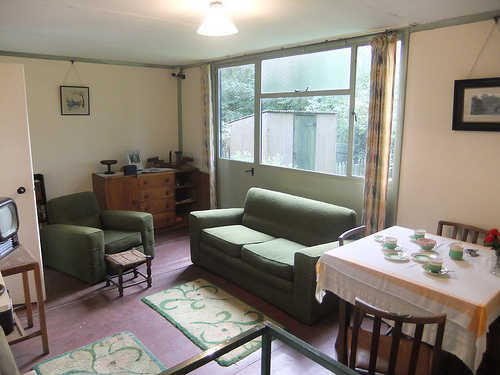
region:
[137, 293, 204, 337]
blue edge of small rug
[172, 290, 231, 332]
blue design on white rug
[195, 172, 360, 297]
large green sofa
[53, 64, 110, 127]
picture hanging on black hook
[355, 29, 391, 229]
tall pink and gray drape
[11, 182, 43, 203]
black door knob on pink door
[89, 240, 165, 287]
small stool with pink cover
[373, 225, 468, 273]
pink and green cups and saucers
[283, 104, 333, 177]
blue door on white shed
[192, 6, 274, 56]
large white light fixture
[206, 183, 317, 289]
green couch by window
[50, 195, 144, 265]
green chair in living room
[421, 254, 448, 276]
tea cup on table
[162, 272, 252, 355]
rug in front of couch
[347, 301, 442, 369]
wooden chair by table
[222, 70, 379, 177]
window behind couch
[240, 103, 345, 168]
shed behind house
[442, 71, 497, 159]
picture on wall behind table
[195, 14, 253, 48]
light on living room ceiling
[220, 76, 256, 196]
door to go outside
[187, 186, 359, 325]
A green loveseat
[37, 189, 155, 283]
A green chair that matches the loveseat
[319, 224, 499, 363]
A kitchen table with a white and gold cloth on it.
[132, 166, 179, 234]
A brown dresser against a wall.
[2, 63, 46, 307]
A white open door.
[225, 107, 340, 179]
A shed visible through the window.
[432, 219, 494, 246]
The top of a brown chair against a wall.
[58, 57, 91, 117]
A picture hanging on the wall.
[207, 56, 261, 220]
A door that leads outside.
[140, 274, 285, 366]
A white and green rug in front of a loveseat.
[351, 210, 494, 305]
A tea set on a table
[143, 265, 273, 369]
A area rug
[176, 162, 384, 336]
A green loveseat sofa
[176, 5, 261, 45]
a ceiling lamp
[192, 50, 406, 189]
A picture window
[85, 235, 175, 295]
a footstool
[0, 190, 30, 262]
Part of a small TV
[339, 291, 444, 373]
A dining room chair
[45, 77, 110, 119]
A painting hung on a wall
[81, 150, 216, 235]
A bureau topped with pictures and knicknacks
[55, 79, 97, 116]
painting hanging on wall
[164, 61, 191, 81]
security camera in corner of room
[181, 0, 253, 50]
light with white cover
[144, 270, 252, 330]
green and yellow rug on ground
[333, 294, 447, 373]
brown wooden dining chair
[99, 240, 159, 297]
brown wooden foot stool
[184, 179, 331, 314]
green sofa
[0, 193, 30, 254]
small television monitor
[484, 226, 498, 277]
small rose on table top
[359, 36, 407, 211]
curtains hanging on wall